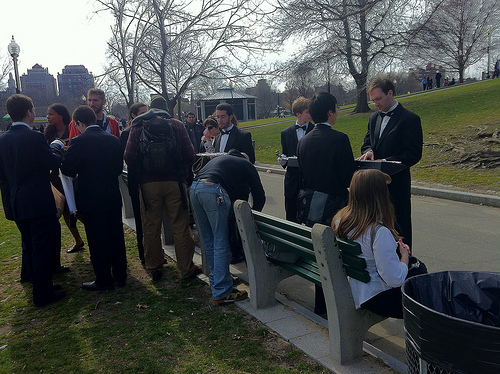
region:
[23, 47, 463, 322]
There are people in a park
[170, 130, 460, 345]
There is a lady sitting on a park bench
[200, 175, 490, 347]
There is a trash can next to the bench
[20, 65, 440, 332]
There are men dressed in suits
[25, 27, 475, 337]
The photo was taken in a park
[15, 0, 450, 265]
There are buildings in the background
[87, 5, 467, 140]
There are trees with no leaves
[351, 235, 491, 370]
The trashcan has a trash bag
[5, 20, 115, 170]
There is a light pole in the background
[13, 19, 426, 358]
The photo was taken during the daytime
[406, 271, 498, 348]
Trash can with trash liner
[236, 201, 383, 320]
Park bench with one female sitting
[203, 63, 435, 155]
Men in tuxes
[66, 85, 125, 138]
Man wearing red jacket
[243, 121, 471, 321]
Narrow road appears to be in a cemetary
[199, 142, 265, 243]
man bending over bench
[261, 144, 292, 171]
boy holding a bell or microphone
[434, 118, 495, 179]
Tree roots in ground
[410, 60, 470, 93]
People in the background under tree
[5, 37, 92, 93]
Light pole and buildings in background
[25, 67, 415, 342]
people gathered at a park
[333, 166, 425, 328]
woman sitting on a bench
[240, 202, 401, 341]
concrete and green wooden bench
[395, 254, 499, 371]
trash barrel with black trash bag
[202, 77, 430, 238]
three men in a tuxedo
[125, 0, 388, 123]
tall trees with no leaves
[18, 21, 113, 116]
tall brick buildings in the background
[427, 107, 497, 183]
brown roots of trees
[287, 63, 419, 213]
men playing musical instruments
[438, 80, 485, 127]
green grassy hill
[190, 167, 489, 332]
Bench with a woman on it.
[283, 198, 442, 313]
Woman on the bench.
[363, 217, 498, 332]
Trash can on the sidewalk.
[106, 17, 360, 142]
Trees in the background.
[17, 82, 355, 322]
Several people on the sidewalk.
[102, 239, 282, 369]
Green grass on the ground.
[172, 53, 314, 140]
Building on the grass.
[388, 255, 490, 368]
Black bag in the trash can.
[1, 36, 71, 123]
Light on the post.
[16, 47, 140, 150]
Buildings behind the people.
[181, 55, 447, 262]
men in formal clothing holding trays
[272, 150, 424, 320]
woman sitting on end of bench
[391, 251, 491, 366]
plastic bag lining garbage can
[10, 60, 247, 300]
people standing around in a park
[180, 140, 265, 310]
man leaning over a bench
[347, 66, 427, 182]
man touching tray with finger tips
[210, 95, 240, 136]
man with long hair and a beard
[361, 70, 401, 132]
man wearing a bow tie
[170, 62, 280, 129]
pavilion on a grassy hill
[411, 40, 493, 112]
people under a tree at the top of the hill